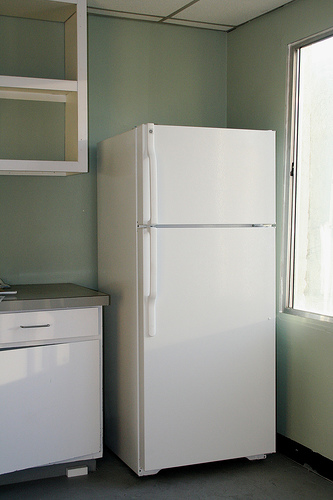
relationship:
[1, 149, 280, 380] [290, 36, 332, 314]
light shining through window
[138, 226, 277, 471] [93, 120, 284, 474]
door on refrigerator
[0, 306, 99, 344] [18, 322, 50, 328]
drawer with handle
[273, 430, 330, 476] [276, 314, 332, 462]
moulding on wall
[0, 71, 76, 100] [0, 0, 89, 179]
shelf inside cabinets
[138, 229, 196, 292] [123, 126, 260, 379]
door on fridge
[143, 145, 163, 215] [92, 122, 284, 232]
handle on freezer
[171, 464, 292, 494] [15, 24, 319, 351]
floor in room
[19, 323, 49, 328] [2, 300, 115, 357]
handle on drawer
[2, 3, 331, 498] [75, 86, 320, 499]
kitchen with refrigerator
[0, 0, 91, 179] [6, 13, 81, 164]
cabinets without doors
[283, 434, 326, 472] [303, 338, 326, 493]
black border along wall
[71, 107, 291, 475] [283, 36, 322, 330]
refrigerator next to window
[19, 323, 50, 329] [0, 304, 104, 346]
handle on drawer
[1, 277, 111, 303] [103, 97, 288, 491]
counter next to refrigerator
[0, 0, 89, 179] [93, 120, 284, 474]
cabinets next to refrigerator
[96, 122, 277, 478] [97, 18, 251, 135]
refrigerator against wall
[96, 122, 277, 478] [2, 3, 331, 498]
refrigerator on corner of kitchen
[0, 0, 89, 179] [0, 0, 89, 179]
cabinets of cabinets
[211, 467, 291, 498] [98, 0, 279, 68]
tiles over frame